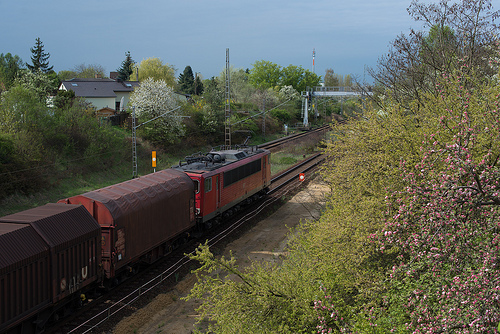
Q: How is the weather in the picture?
A: It is clear.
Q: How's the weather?
A: It is clear.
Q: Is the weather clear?
A: Yes, it is clear.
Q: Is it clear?
A: Yes, it is clear.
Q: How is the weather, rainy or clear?
A: It is clear.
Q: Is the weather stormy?
A: No, it is clear.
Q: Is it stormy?
A: No, it is clear.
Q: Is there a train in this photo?
A: Yes, there is a train.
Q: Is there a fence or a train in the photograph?
A: Yes, there is a train.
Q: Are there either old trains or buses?
A: Yes, there is an old train.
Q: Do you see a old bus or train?
A: Yes, there is an old train.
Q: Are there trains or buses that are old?
A: Yes, the train is old.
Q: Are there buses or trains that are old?
A: Yes, the train is old.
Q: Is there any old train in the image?
A: Yes, there is an old train.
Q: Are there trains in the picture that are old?
A: Yes, there is a train that is old.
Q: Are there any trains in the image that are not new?
A: Yes, there is a old train.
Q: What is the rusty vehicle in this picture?
A: The vehicle is a train.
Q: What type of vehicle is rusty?
A: The vehicle is a train.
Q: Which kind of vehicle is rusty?
A: The vehicle is a train.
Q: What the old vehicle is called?
A: The vehicle is a train.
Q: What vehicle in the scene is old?
A: The vehicle is a train.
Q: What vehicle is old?
A: The vehicle is a train.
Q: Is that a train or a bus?
A: That is a train.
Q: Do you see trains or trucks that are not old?
A: No, there is a train but it is old.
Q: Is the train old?
A: Yes, the train is old.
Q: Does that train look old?
A: Yes, the train is old.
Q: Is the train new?
A: No, the train is old.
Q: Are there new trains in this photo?
A: No, there is a train but it is old.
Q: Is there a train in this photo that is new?
A: No, there is a train but it is old.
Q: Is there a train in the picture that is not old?
A: No, there is a train but it is old.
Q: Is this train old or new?
A: The train is old.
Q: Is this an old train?
A: Yes, this is an old train.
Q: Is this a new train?
A: No, this is an old train.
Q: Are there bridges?
A: Yes, there is a bridge.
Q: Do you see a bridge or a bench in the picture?
A: Yes, there is a bridge.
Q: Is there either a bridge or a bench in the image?
A: Yes, there is a bridge.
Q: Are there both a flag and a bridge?
A: No, there is a bridge but no flags.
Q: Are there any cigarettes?
A: No, there are no cigarettes.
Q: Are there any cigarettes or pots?
A: No, there are no cigarettes or pots.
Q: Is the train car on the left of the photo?
A: Yes, the train car is on the left of the image.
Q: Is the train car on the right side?
A: No, the train car is on the left of the image.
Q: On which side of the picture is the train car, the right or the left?
A: The train car is on the left of the image.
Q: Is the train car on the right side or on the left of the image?
A: The train car is on the left of the image.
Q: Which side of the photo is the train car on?
A: The train car is on the left of the image.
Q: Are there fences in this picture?
A: No, there are no fences.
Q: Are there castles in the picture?
A: No, there are no castles.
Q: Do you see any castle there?
A: No, there are no castles.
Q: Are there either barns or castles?
A: No, there are no castles or barns.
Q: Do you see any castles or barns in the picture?
A: No, there are no castles or barns.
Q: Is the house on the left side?
A: Yes, the house is on the left of the image.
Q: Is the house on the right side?
A: No, the house is on the left of the image.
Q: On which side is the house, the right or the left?
A: The house is on the left of the image.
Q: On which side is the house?
A: The house is on the left of the image.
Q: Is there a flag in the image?
A: No, there are no flags.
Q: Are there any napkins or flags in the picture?
A: No, there are no flags or napkins.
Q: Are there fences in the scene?
A: No, there are no fences.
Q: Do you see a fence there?
A: No, there are no fences.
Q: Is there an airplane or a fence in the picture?
A: No, there are no fences or airplanes.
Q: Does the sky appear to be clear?
A: Yes, the sky is clear.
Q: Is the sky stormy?
A: No, the sky is clear.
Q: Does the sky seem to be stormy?
A: No, the sky is clear.